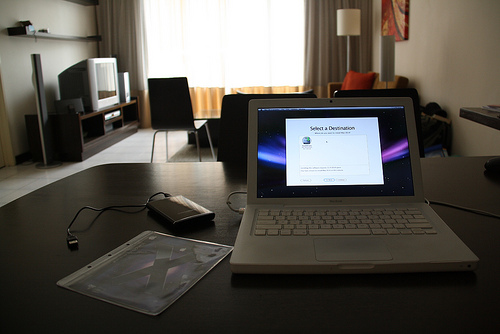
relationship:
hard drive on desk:
[140, 192, 216, 229] [9, 159, 483, 329]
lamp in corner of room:
[314, 0, 392, 78] [1, 1, 482, 329]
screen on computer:
[253, 103, 415, 196] [228, 97, 480, 273]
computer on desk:
[228, 97, 480, 273] [0, 154, 499, 334]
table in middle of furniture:
[186, 114, 221, 146] [151, 77, 256, 149]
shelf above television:
[2, 21, 104, 45] [56, 52, 116, 108]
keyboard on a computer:
[199, 190, 464, 248] [228, 97, 480, 273]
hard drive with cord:
[146, 194, 215, 227] [67, 191, 170, 244]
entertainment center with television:
[48, 50, 129, 160] [58, 57, 121, 113]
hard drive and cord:
[146, 194, 215, 227] [62, 186, 169, 260]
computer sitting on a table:
[185, 62, 481, 291] [1, 152, 495, 332]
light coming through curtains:
[145, 2, 296, 91] [146, 4, 300, 100]